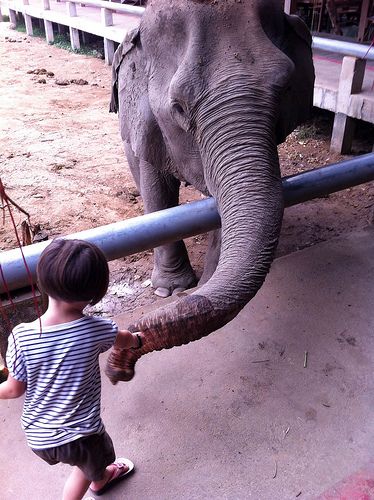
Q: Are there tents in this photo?
A: No, there are no tents.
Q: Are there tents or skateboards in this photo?
A: No, there are no tents or skateboards.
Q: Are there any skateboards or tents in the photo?
A: No, there are no tents or skateboards.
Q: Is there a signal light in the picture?
A: No, there are no traffic lights.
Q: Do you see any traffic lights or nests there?
A: No, there are no traffic lights or nests.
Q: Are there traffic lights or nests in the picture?
A: No, there are no traffic lights or nests.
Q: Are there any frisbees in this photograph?
A: No, there are no frisbees.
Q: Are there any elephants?
A: Yes, there is an elephant.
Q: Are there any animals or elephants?
A: Yes, there is an elephant.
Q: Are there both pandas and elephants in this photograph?
A: No, there is an elephant but no pandas.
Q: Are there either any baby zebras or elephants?
A: Yes, there is a baby elephant.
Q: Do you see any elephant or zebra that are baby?
A: Yes, the elephant is a baby.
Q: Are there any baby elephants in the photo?
A: Yes, there is a baby elephant.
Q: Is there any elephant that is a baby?
A: Yes, there is an elephant that is a baby.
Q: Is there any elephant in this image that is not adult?
A: Yes, there is an baby elephant.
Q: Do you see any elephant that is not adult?
A: Yes, there is an baby elephant.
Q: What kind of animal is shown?
A: The animal is an elephant.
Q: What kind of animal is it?
A: The animal is an elephant.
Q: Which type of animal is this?
A: This is an elephant.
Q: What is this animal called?
A: This is an elephant.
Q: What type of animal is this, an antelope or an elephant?
A: This is an elephant.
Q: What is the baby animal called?
A: The animal is an elephant.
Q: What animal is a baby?
A: The animal is an elephant.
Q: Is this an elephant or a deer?
A: This is an elephant.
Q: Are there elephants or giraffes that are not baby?
A: No, there is an elephant but it is a baby.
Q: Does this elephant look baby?
A: Yes, the elephant is a baby.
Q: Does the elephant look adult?
A: No, the elephant is a baby.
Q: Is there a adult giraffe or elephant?
A: No, there is an elephant but it is a baby.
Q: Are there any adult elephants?
A: No, there is an elephant but it is a baby.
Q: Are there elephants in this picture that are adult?
A: No, there is an elephant but it is a baby.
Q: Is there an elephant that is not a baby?
A: No, there is an elephant but it is a baby.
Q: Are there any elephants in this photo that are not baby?
A: No, there is an elephant but it is a baby.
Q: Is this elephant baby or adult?
A: The elephant is a baby.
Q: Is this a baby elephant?
A: Yes, this is a baby elephant.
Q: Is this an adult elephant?
A: No, this is a baby elephant.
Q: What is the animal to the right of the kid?
A: The animal is an elephant.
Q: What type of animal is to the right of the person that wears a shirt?
A: The animal is an elephant.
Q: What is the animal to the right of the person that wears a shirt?
A: The animal is an elephant.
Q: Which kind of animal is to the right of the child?
A: The animal is an elephant.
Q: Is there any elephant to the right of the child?
A: Yes, there is an elephant to the right of the child.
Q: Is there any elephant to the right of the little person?
A: Yes, there is an elephant to the right of the child.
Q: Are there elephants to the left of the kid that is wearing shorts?
A: No, the elephant is to the right of the kid.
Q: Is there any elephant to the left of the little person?
A: No, the elephant is to the right of the kid.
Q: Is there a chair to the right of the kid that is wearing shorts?
A: No, there is an elephant to the right of the kid.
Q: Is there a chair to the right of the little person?
A: No, there is an elephant to the right of the kid.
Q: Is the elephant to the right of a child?
A: Yes, the elephant is to the right of a child.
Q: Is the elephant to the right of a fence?
A: No, the elephant is to the right of a child.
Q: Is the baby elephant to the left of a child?
A: No, the elephant is to the right of a child.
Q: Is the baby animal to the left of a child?
A: No, the elephant is to the right of a child.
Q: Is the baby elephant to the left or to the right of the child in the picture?
A: The elephant is to the right of the child.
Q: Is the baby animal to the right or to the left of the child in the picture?
A: The elephant is to the right of the child.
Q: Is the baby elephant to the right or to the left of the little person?
A: The elephant is to the right of the child.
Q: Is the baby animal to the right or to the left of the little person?
A: The elephant is to the right of the child.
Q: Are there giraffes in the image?
A: No, there are no giraffes.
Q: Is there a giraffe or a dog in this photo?
A: No, there are no giraffes or dogs.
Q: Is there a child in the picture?
A: Yes, there is a child.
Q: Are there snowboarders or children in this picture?
A: Yes, there is a child.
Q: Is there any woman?
A: No, there are no women.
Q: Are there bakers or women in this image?
A: No, there are no women or bakers.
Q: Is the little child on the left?
A: Yes, the kid is on the left of the image.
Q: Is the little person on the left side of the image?
A: Yes, the kid is on the left of the image.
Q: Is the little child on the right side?
A: No, the kid is on the left of the image.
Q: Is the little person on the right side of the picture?
A: No, the kid is on the left of the image.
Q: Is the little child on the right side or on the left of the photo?
A: The child is on the left of the image.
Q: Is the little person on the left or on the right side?
A: The child is on the left of the image.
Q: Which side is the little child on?
A: The kid is on the left of the image.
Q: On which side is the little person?
A: The kid is on the left of the image.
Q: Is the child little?
A: Yes, the child is little.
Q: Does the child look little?
A: Yes, the child is little.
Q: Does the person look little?
A: Yes, the kid is little.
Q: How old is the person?
A: The kid is little.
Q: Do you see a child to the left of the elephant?
A: Yes, there is a child to the left of the elephant.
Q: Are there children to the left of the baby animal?
A: Yes, there is a child to the left of the elephant.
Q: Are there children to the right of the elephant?
A: No, the child is to the left of the elephant.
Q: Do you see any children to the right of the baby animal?
A: No, the child is to the left of the elephant.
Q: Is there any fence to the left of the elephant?
A: No, there is a child to the left of the elephant.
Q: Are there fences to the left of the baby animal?
A: No, there is a child to the left of the elephant.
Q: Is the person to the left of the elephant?
A: Yes, the child is to the left of the elephant.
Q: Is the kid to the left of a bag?
A: No, the kid is to the left of the elephant.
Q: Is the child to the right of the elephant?
A: No, the child is to the left of the elephant.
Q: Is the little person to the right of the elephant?
A: No, the child is to the left of the elephant.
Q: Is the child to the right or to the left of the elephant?
A: The child is to the left of the elephant.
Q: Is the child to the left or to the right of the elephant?
A: The child is to the left of the elephant.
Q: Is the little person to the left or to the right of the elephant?
A: The child is to the left of the elephant.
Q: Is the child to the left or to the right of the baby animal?
A: The child is to the left of the elephant.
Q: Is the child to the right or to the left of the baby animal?
A: The child is to the left of the elephant.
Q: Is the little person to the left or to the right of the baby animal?
A: The child is to the left of the elephant.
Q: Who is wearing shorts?
A: The child is wearing shorts.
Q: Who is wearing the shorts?
A: The child is wearing shorts.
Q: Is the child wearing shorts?
A: Yes, the child is wearing shorts.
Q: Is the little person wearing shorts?
A: Yes, the child is wearing shorts.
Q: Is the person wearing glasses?
A: No, the kid is wearing shorts.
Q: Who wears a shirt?
A: The child wears a shirt.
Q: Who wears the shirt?
A: The child wears a shirt.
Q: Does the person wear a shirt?
A: Yes, the kid wears a shirt.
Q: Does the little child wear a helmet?
A: No, the kid wears a shirt.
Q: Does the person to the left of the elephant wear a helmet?
A: No, the kid wears a shirt.